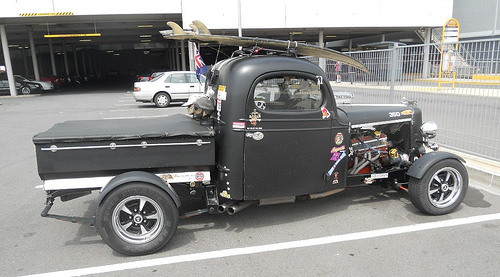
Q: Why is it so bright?
A: Sunny.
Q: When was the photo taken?
A: Day time.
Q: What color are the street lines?
A: White.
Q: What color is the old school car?
A: Black.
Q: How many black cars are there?
A: One.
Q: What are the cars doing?
A: Parked.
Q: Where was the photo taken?
A: In a parking lot.